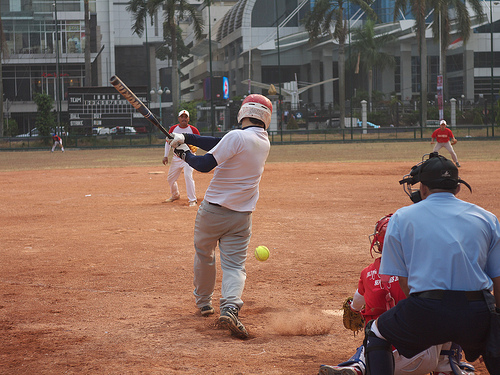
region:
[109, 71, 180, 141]
Metal baseball bat in air.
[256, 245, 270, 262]
Green softball in air.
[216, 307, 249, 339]
Black baseball cleats on ground.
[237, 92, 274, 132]
Red and white baseball helmet.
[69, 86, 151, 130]
Baseball scoreboard in park.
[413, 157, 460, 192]
Black baseball hat on head.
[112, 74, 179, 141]
Softball bat in the air.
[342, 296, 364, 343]
Catchers baseball glove.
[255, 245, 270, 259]
Green softball in mid air.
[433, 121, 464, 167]
Baseball player in uniform.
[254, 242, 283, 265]
a baseball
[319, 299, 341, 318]
home plate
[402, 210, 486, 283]
a shirt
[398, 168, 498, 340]
the umpire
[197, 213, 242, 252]
batter is wearing grey pants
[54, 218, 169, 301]
the dirt is brown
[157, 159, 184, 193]
the pitcher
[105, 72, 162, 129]
a baseball bat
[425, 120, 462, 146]
a person wearing a red shirt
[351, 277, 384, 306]
the catcher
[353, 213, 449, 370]
catcher wearing a red uniform and mask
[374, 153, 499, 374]
baseball umpire in blue short sleeve shirt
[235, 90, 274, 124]
a white and red protective helmet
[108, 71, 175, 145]
a black baseball bat with writing on it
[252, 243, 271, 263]
a light green baseball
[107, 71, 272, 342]
baseball player swinging bat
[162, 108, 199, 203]
a baseball pitcher in red and white uniform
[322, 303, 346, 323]
home plate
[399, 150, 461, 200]
a black umpire's mask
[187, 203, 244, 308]
a pair of grey baseball pants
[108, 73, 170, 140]
a black baseball bat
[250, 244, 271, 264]
a yellow baseball in flight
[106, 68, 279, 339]
a baseball player at bat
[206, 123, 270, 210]
a white t-shirt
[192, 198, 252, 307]
a beige pair of pants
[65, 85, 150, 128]
a black and white scoreboard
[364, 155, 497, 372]
an umpire crouching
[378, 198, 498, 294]
a short sleeved blue shirt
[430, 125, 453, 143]
a bright red baseball jersey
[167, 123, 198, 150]
a red and white baseball jersey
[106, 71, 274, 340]
a person with a baseball bat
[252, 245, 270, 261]
a baseball in the air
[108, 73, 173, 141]
a black and yellow baseball bat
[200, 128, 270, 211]
a white short sleeve shirt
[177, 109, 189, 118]
a white baseball cap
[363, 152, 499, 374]
a person wearing shorts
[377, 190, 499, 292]
a blue short sleeve shirt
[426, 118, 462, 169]
a person in a red shirt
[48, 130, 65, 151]
a person in a red shirt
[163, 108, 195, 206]
a person wearing white a red